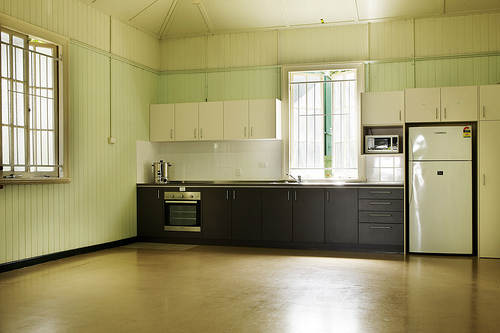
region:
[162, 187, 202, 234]
silver oven built into shelves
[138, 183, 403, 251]
dark cabinets in the kitchen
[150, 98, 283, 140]
white cabinets hanging on the wall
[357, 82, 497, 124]
white cabinets hanging on the wall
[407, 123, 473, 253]
white fridge below the cabinets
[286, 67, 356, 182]
window above the sink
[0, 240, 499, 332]
brown floor has a glare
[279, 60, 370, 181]
A window on the wall of a kitchen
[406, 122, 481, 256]
A white refrigerator in a kitchen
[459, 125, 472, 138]
A magnet on a refrigerator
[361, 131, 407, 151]
A microwave oven on a shelf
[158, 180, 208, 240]
A stove in an empty kitchen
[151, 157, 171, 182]
A silver coffee maker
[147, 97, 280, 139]
White kitchen cupboards on a wall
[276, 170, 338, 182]
A sink with a silver faucet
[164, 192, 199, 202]
Three knobs on a stove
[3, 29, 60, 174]
An open window in a kitchen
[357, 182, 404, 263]
the drawers are closed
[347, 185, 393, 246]
the drawers are closed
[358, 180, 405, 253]
the drawers are closed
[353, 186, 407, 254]
the drawers are closed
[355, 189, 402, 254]
the drawers are closed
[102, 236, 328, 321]
the floor is shiny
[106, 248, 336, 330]
the floor is shiny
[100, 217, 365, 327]
the floor is shiny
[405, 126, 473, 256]
a white refrigerator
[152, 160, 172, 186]
a silver coffee pot on a counter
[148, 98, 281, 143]
white kitchen cabinets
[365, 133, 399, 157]
a microwave oven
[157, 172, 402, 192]
a long counter top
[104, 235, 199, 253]
a rug on the floor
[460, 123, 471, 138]
a sticker on a refrigerator door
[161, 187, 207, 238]
a oven with a glass door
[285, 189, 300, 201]
silver cabinet handles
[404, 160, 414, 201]
a handle on a refrigerator door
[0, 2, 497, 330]
interior of brightly lit kitchen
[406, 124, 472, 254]
front of white refrigerator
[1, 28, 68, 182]
open window on wall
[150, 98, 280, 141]
row of white kitchen cabinets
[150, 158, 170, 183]
silver appliance in corner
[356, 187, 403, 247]
handles on kitchen drawers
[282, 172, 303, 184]
faucet of kitchen sink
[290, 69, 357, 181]
natural light in window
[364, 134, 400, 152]
redctangle appliance in window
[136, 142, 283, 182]
white backsplash of kitchen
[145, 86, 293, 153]
the cabinets are white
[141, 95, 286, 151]
the cabinets are white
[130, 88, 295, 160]
the cabinets are white